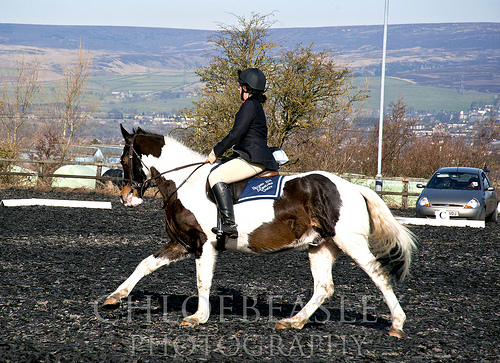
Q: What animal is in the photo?
A: Horse.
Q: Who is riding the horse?
A: A person.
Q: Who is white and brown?
A: Horse.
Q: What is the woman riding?
A: A horse.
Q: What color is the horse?
A: White and brown.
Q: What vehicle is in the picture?
A: A car.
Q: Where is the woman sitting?
A: On the horse.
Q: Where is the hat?
A: On the woman's head.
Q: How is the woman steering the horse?
A: Reins.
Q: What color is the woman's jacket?
A: Black.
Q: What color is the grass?
A: Green.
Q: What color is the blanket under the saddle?
A: Blue.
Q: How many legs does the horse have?
A: 4.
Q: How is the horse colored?
A: Brown and white.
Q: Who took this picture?
A: Chloe Beasley Photography.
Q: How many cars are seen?
A: One.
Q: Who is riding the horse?
A: A woman.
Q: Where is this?
A: A gravel parking lot.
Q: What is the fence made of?
A: Wood.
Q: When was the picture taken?
A: Daytime.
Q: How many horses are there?
A: One.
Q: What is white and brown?
A: Horse.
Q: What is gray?
A: A car.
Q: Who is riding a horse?
A: A person.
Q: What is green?
A: Grass.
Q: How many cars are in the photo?
A: Only one.